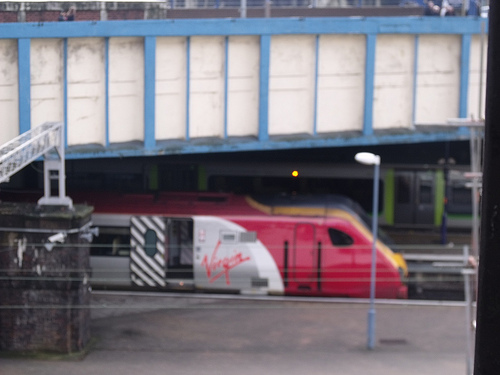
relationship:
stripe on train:
[243, 194, 408, 275] [0, 196, 410, 297]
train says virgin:
[0, 196, 410, 297] [198, 236, 255, 286]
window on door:
[143, 225, 157, 257] [127, 210, 162, 289]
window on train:
[328, 223, 355, 246] [0, 196, 410, 297]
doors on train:
[393, 165, 435, 224] [16, 162, 482, 231]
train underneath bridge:
[0, 196, 410, 297] [0, 0, 499, 164]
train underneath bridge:
[16, 162, 482, 231] [0, 0, 499, 164]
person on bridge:
[56, 4, 77, 21] [0, 0, 499, 164]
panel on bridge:
[68, 39, 105, 146] [0, 0, 499, 164]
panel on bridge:
[109, 35, 143, 147] [0, 0, 499, 164]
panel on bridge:
[155, 37, 186, 139] [0, 0, 499, 164]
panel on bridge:
[189, 35, 225, 137] [0, 0, 499, 164]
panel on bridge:
[267, 33, 315, 132] [0, 0, 499, 164]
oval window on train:
[143, 225, 157, 257] [0, 196, 410, 297]